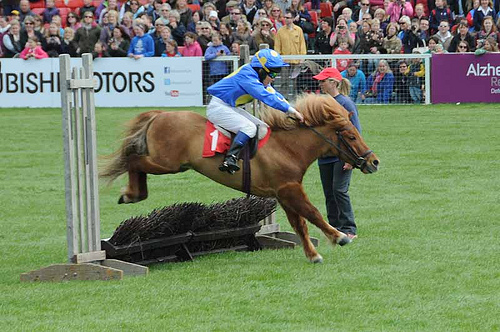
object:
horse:
[97, 90, 380, 265]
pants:
[206, 96, 257, 140]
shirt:
[204, 64, 289, 114]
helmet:
[250, 47, 290, 67]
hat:
[312, 67, 343, 80]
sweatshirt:
[317, 92, 361, 166]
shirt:
[127, 33, 155, 58]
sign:
[428, 53, 500, 104]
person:
[204, 33, 232, 83]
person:
[182, 31, 203, 57]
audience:
[1, 0, 498, 102]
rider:
[207, 47, 306, 175]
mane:
[254, 93, 348, 129]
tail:
[96, 110, 159, 194]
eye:
[347, 135, 356, 141]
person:
[312, 67, 361, 243]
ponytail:
[338, 78, 354, 96]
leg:
[119, 168, 150, 204]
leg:
[275, 180, 354, 252]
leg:
[286, 212, 323, 264]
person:
[397, 15, 412, 38]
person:
[19, 35, 50, 60]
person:
[329, 19, 355, 46]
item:
[107, 190, 276, 259]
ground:
[0, 106, 499, 328]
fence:
[23, 50, 320, 280]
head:
[258, 65, 278, 88]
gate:
[58, 50, 107, 265]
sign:
[1, 57, 204, 108]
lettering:
[0, 70, 156, 95]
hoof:
[339, 233, 355, 248]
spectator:
[382, 21, 402, 54]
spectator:
[249, 16, 276, 54]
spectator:
[72, 9, 102, 56]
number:
[209, 129, 218, 151]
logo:
[163, 65, 171, 75]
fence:
[0, 47, 500, 108]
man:
[274, 9, 308, 94]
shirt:
[272, 25, 308, 63]